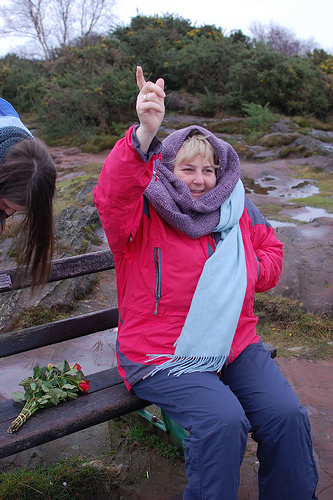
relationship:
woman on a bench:
[95, 60, 317, 465] [0, 245, 278, 468]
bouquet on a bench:
[8, 350, 91, 436] [1, 384, 132, 439]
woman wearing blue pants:
[95, 60, 317, 465] [115, 333, 324, 499]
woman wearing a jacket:
[95, 60, 317, 465] [92, 123, 292, 383]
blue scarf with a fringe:
[189, 219, 242, 357] [132, 354, 222, 379]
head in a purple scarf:
[155, 121, 243, 236] [140, 122, 239, 237]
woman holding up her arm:
[95, 60, 317, 465] [94, 51, 169, 246]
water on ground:
[237, 165, 325, 205] [241, 108, 332, 333]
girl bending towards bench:
[0, 99, 57, 234] [1, 384, 132, 439]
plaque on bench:
[2, 272, 13, 288] [1, 384, 132, 439]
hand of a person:
[121, 60, 170, 141] [95, 60, 317, 465]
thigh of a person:
[152, 359, 244, 443] [95, 60, 317, 465]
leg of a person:
[247, 351, 324, 497] [95, 60, 317, 465]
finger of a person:
[133, 61, 150, 88] [95, 60, 317, 465]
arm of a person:
[94, 51, 169, 246] [95, 60, 317, 465]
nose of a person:
[193, 171, 207, 186] [95, 60, 317, 465]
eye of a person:
[186, 166, 195, 172] [95, 60, 317, 465]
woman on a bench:
[95, 60, 317, 465] [1, 384, 132, 439]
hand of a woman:
[121, 60, 170, 141] [95, 60, 317, 465]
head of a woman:
[155, 121, 243, 236] [95, 60, 317, 465]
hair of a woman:
[186, 138, 210, 151] [95, 60, 317, 465]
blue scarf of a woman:
[189, 219, 242, 357] [95, 60, 317, 465]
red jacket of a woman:
[92, 123, 292, 383] [95, 60, 317, 465]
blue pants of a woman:
[132, 338, 320, 500] [95, 60, 317, 465]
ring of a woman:
[142, 90, 149, 105] [95, 60, 317, 465]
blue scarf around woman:
[189, 219, 242, 357] [95, 60, 317, 465]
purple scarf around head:
[173, 126, 218, 143] [155, 121, 243, 236]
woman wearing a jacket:
[95, 60, 317, 465] [92, 123, 284, 392]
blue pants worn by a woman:
[115, 333, 324, 499] [95, 60, 317, 465]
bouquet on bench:
[8, 350, 91, 436] [1, 384, 132, 439]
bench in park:
[1, 384, 132, 439] [2, 3, 329, 315]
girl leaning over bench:
[4, 103, 59, 242] [1, 384, 132, 439]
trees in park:
[41, 11, 316, 103] [2, 3, 329, 315]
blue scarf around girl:
[1, 100, 19, 149] [4, 103, 59, 242]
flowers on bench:
[65, 360, 89, 400] [0, 245, 278, 468]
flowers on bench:
[76, 378, 91, 396] [1, 384, 132, 439]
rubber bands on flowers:
[13, 404, 39, 429] [65, 360, 89, 400]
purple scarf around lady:
[140, 122, 239, 237] [95, 60, 317, 465]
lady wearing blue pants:
[95, 60, 317, 465] [132, 338, 320, 500]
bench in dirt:
[0, 245, 278, 468] [112, 448, 174, 488]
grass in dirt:
[263, 297, 331, 360] [296, 360, 332, 407]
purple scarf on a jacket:
[140, 122, 239, 237] [92, 123, 292, 383]